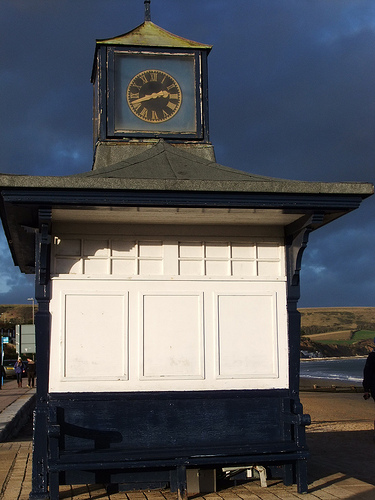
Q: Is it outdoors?
A: Yes, it is outdoors.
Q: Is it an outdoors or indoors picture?
A: It is outdoors.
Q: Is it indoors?
A: No, it is outdoors.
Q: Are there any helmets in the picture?
A: No, there are no helmets.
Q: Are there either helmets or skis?
A: No, there are no helmets or skis.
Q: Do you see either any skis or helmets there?
A: No, there are no helmets or skis.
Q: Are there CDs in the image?
A: No, there are no cds.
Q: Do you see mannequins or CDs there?
A: No, there are no CDs or mannequins.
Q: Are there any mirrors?
A: No, there are no mirrors.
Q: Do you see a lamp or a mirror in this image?
A: No, there are no mirrors or lamps.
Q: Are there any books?
A: No, there are no books.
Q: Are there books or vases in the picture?
A: No, there are no books or vases.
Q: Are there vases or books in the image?
A: No, there are no books or vases.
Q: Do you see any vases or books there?
A: No, there are no books or vases.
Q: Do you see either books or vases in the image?
A: No, there are no books or vases.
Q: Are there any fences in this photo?
A: No, there are no fences.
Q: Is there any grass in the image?
A: Yes, there is grass.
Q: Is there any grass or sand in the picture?
A: Yes, there is grass.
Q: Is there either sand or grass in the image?
A: Yes, there is grass.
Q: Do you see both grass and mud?
A: No, there is grass but no mud.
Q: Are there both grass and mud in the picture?
A: No, there is grass but no mud.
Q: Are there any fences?
A: No, there are no fences.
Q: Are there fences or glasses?
A: No, there are no fences or glasses.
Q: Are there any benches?
A: Yes, there is a bench.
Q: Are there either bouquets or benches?
A: Yes, there is a bench.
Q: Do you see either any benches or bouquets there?
A: Yes, there is a bench.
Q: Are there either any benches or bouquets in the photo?
A: Yes, there is a bench.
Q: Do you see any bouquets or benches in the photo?
A: Yes, there is a bench.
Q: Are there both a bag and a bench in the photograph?
A: No, there is a bench but no bags.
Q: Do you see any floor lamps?
A: No, there are no floor lamps.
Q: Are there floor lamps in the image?
A: No, there are no floor lamps.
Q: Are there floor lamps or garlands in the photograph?
A: No, there are no floor lamps or garlands.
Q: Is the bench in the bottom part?
A: Yes, the bench is in the bottom of the image.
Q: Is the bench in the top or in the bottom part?
A: The bench is in the bottom of the image.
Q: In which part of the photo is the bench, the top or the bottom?
A: The bench is in the bottom of the image.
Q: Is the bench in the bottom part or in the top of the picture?
A: The bench is in the bottom of the image.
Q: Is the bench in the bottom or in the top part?
A: The bench is in the bottom of the image.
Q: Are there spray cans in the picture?
A: No, there are no spray cans.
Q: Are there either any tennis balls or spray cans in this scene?
A: No, there are no spray cans or tennis balls.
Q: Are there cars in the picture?
A: No, there are no cars.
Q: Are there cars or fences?
A: No, there are no cars or fences.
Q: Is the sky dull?
A: Yes, the sky is dull.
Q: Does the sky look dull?
A: Yes, the sky is dull.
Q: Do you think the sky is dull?
A: Yes, the sky is dull.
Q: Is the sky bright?
A: No, the sky is dull.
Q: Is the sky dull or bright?
A: The sky is dull.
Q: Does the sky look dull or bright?
A: The sky is dull.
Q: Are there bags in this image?
A: No, there are no bags.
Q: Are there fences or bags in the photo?
A: No, there are no bags or fences.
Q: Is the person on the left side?
A: Yes, the person is on the left of the image.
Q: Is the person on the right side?
A: No, the person is on the left of the image.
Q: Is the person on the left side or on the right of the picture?
A: The person is on the left of the image.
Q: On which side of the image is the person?
A: The person is on the left of the image.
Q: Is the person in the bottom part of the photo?
A: Yes, the person is in the bottom of the image.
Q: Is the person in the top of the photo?
A: No, the person is in the bottom of the image.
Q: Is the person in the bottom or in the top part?
A: The person is in the bottom of the image.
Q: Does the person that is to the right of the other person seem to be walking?
A: Yes, the person is walking.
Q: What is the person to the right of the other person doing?
A: The person is walking.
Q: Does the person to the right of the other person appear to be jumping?
A: No, the person is walking.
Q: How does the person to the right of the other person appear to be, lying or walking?
A: The person is walking.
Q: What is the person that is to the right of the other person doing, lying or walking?
A: The person is walking.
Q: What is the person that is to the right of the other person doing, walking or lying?
A: The person is walking.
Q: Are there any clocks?
A: Yes, there is a clock.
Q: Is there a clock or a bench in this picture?
A: Yes, there is a clock.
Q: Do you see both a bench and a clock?
A: Yes, there are both a clock and a bench.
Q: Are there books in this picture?
A: No, there are no books.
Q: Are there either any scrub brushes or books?
A: No, there are no books or scrub brushes.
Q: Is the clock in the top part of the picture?
A: Yes, the clock is in the top of the image.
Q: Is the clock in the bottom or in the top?
A: The clock is in the top of the image.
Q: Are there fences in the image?
A: No, there are no fences.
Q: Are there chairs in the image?
A: No, there are no chairs.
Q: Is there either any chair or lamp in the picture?
A: No, there are no chairs or lamps.